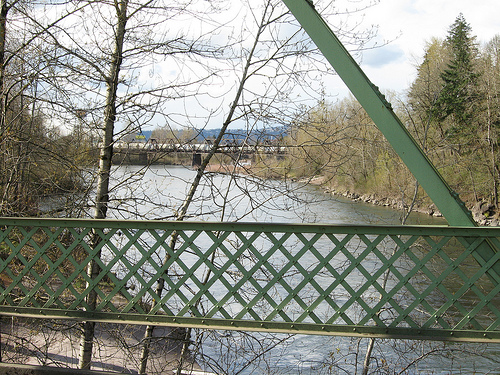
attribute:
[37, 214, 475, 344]
fence — green metal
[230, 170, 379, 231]
river water — calm, blue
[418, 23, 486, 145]
pine tree — tall, green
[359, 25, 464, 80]
clouds — white, fluffy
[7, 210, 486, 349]
fence — green metal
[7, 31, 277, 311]
trees — brown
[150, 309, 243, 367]
river bank — brown